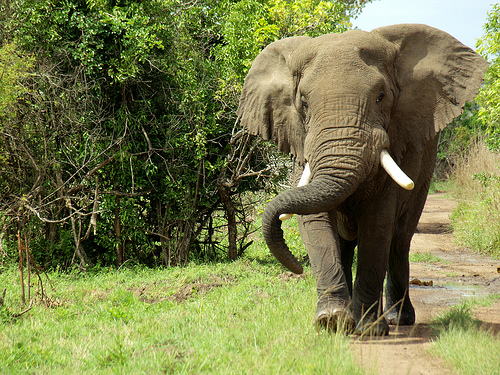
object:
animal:
[235, 23, 490, 334]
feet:
[311, 303, 355, 333]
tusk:
[375, 148, 414, 190]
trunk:
[258, 159, 366, 274]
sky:
[347, 1, 497, 53]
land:
[342, 193, 498, 375]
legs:
[294, 210, 359, 332]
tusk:
[380, 150, 415, 193]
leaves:
[121, 51, 129, 63]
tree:
[136, 34, 218, 263]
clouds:
[397, 1, 497, 22]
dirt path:
[353, 182, 499, 373]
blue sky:
[352, 0, 488, 45]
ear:
[370, 22, 491, 168]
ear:
[234, 35, 304, 167]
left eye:
[370, 88, 383, 103]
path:
[322, 192, 476, 375]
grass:
[1, 268, 341, 373]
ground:
[1, 189, 500, 372]